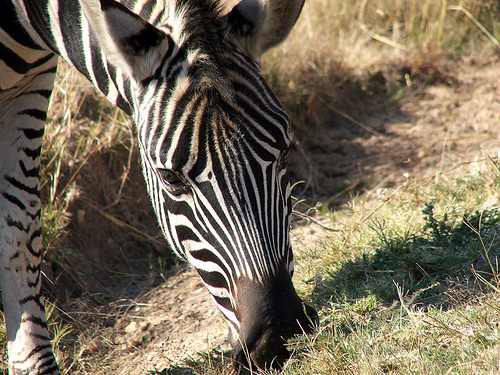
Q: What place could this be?
A: It is a field.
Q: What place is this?
A: It is a field.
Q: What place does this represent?
A: It represents the field.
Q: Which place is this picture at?
A: It is at the field.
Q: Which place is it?
A: It is a field.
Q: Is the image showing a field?
A: Yes, it is showing a field.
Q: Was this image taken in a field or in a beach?
A: It was taken at a field.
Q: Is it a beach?
A: No, it is a field.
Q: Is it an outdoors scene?
A: Yes, it is outdoors.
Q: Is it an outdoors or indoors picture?
A: It is outdoors.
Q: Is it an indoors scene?
A: No, it is outdoors.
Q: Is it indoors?
A: No, it is outdoors.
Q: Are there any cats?
A: No, there are no cats.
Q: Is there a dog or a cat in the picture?
A: No, there are no cats or dogs.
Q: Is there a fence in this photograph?
A: No, there are no fences.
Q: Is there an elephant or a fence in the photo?
A: No, there are no fences or elephants.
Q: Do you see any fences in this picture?
A: No, there are no fences.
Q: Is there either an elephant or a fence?
A: No, there are no fences or elephants.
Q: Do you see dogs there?
A: No, there are no dogs.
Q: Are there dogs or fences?
A: No, there are no dogs or fences.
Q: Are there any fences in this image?
A: No, there are no fences.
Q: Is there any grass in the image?
A: Yes, there is grass.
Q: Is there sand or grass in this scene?
A: Yes, there is grass.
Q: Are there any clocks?
A: No, there are no clocks.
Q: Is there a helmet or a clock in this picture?
A: No, there are no clocks or helmets.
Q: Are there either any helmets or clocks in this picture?
A: No, there are no clocks or helmets.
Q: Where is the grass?
A: The grass is on the ground.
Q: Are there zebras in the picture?
A: Yes, there is a zebra.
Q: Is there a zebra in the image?
A: Yes, there is a zebra.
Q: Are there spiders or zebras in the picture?
A: Yes, there is a zebra.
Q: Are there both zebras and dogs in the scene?
A: No, there is a zebra but no dogs.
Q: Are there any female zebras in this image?
A: Yes, there is a female zebra.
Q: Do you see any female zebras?
A: Yes, there is a female zebra.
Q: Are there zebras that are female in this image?
A: Yes, there is a female zebra.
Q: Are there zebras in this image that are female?
A: Yes, there is a zebra that is female.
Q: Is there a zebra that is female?
A: Yes, there is a zebra that is female.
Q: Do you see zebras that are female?
A: Yes, there is a zebra that is female.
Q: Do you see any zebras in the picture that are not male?
A: Yes, there is a female zebra.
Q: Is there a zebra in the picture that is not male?
A: Yes, there is a female zebra.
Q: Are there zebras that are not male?
A: Yes, there is a female zebra.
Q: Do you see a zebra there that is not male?
A: Yes, there is a female zebra.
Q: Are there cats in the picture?
A: No, there are no cats.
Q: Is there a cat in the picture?
A: No, there are no cats.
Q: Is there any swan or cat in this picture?
A: No, there are no cats or swans.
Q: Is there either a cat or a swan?
A: No, there are no cats or swans.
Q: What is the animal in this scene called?
A: The animal is a zebra.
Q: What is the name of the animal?
A: The animal is a zebra.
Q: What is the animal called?
A: The animal is a zebra.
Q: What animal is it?
A: The animal is a zebra.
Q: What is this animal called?
A: This is a zebra.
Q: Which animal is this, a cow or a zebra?
A: This is a zebra.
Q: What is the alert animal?
A: The animal is a zebra.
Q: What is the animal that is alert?
A: The animal is a zebra.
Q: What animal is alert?
A: The animal is a zebra.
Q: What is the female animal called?
A: The animal is a zebra.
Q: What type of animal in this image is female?
A: The animal is a zebra.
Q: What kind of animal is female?
A: The animal is a zebra.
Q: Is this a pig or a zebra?
A: This is a zebra.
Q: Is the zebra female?
A: Yes, the zebra is female.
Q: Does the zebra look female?
A: Yes, the zebra is female.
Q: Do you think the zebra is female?
A: Yes, the zebra is female.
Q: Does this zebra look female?
A: Yes, the zebra is female.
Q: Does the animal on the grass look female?
A: Yes, the zebra is female.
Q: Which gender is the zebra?
A: The zebra is female.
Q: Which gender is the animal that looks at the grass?
A: The zebra is female.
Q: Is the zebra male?
A: No, the zebra is female.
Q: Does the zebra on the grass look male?
A: No, the zebra is female.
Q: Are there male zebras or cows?
A: No, there is a zebra but she is female.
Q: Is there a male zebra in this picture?
A: No, there is a zebra but she is female.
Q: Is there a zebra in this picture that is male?
A: No, there is a zebra but she is female.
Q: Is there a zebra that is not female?
A: No, there is a zebra but she is female.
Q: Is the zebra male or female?
A: The zebra is female.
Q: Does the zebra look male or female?
A: The zebra is female.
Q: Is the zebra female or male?
A: The zebra is female.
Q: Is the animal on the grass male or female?
A: The zebra is female.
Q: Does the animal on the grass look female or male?
A: The zebra is female.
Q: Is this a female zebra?
A: Yes, this is a female zebra.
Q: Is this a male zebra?
A: No, this is a female zebra.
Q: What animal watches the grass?
A: The zebra watches the grass.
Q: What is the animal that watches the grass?
A: The animal is a zebra.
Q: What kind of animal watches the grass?
A: The animal is a zebra.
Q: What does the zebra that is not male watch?
A: The zebra watches the grass.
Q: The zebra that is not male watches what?
A: The zebra watches the grass.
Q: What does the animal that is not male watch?
A: The zebra watches the grass.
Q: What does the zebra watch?
A: The zebra watches the grass.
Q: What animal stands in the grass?
A: The zebra stands in the grass.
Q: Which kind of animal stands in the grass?
A: The animal is a zebra.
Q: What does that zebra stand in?
A: The zebra stands in the grass.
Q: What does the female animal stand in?
A: The zebra stands in the grass.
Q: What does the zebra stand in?
A: The zebra stands in the grass.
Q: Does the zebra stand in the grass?
A: Yes, the zebra stands in the grass.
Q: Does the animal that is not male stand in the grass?
A: Yes, the zebra stands in the grass.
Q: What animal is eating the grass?
A: The zebra is eating the grass.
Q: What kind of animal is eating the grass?
A: The animal is a zebra.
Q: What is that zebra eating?
A: The zebra is eating grass.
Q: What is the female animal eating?
A: The zebra is eating grass.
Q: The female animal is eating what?
A: The zebra is eating grass.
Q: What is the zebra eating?
A: The zebra is eating grass.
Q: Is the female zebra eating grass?
A: Yes, the zebra is eating grass.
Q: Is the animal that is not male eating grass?
A: Yes, the zebra is eating grass.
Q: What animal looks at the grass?
A: The zebra looks at the grass.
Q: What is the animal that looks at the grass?
A: The animal is a zebra.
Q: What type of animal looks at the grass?
A: The animal is a zebra.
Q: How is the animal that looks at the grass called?
A: The animal is a zebra.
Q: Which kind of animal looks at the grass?
A: The animal is a zebra.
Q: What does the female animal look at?
A: The zebra looks at the grass.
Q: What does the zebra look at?
A: The zebra looks at the grass.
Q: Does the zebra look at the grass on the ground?
A: Yes, the zebra looks at the grass.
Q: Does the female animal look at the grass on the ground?
A: Yes, the zebra looks at the grass.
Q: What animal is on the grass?
A: The zebra is on the grass.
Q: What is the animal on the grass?
A: The animal is a zebra.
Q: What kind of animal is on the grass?
A: The animal is a zebra.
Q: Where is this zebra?
A: The zebra is on the grass.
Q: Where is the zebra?
A: The zebra is on the grass.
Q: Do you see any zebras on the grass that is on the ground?
A: Yes, there is a zebra on the grass.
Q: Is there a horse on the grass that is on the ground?
A: No, there is a zebra on the grass.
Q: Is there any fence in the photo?
A: No, there are no fences.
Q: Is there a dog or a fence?
A: No, there are no fences or dogs.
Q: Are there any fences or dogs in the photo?
A: No, there are no fences or dogs.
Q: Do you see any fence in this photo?
A: No, there are no fences.